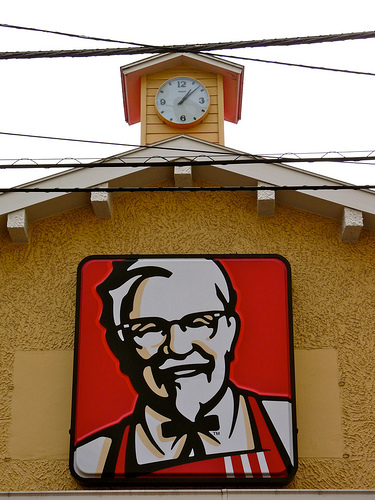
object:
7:
[169, 115, 173, 123]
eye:
[186, 318, 208, 329]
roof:
[0, 134, 375, 243]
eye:
[140, 321, 168, 333]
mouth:
[157, 360, 211, 378]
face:
[157, 77, 207, 120]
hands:
[178, 86, 205, 106]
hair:
[94, 258, 169, 345]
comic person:
[73, 258, 294, 479]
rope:
[0, 30, 375, 60]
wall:
[1, 255, 70, 338]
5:
[192, 113, 197, 121]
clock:
[155, 75, 211, 129]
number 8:
[160, 109, 165, 116]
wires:
[0, 129, 373, 171]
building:
[0, 50, 375, 500]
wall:
[185, 199, 242, 238]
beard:
[175, 387, 200, 423]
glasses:
[116, 310, 227, 350]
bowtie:
[160, 414, 220, 459]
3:
[198, 96, 204, 105]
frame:
[68, 253, 298, 485]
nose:
[163, 323, 194, 358]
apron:
[101, 392, 292, 481]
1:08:
[178, 76, 208, 105]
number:
[160, 97, 166, 105]